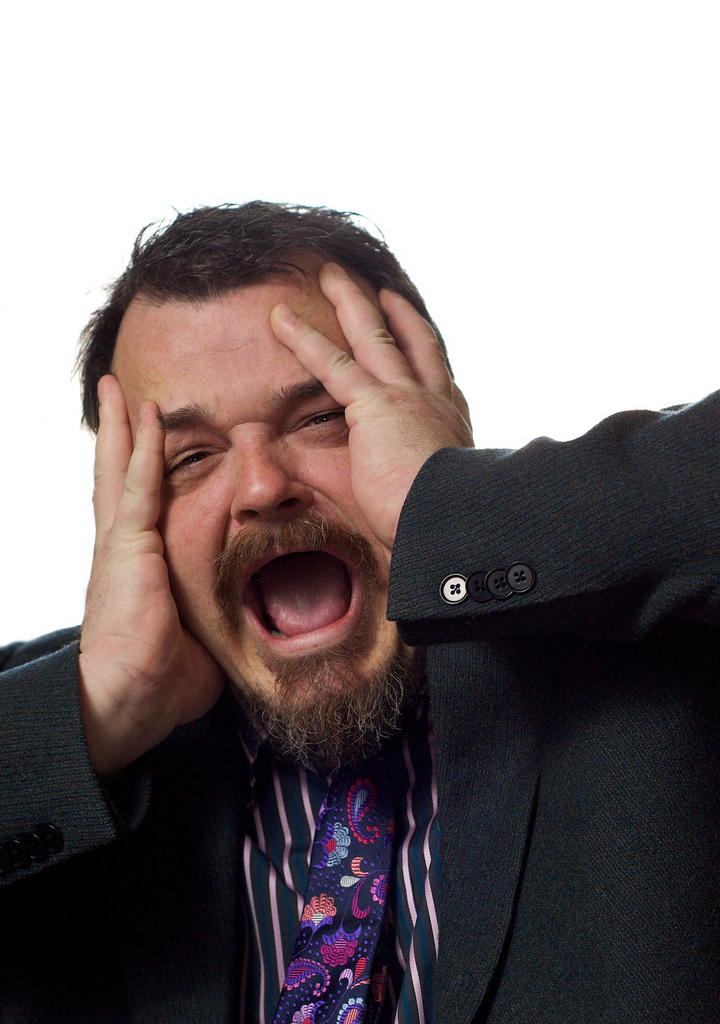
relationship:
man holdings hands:
[3, 200, 715, 1015] [45, 283, 484, 750]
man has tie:
[3, 200, 715, 1015] [270, 751, 398, 1021]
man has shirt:
[3, 200, 715, 1015] [236, 702, 444, 1017]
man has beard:
[3, 200, 715, 1015] [230, 651, 414, 767]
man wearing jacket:
[3, 200, 715, 1015] [0, 387, 718, 1021]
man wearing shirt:
[3, 200, 715, 1015] [236, 702, 444, 1017]